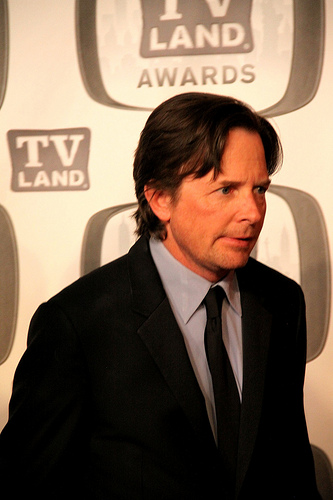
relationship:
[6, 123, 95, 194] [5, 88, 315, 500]
tv land award logo behind man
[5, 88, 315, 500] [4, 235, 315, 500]
man wearing suit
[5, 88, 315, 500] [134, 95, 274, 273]
man has head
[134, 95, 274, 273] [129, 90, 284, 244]
head has hair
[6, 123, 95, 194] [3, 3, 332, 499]
tv land award logo printed on wall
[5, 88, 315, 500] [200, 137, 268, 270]
man has face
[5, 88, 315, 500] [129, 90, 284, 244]
man has hair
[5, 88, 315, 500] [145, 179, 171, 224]
man has ear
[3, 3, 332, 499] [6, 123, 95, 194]
wall has tv land award logo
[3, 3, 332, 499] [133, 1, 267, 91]
wall has logo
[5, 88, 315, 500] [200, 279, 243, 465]
man wearing tie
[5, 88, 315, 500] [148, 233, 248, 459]
man wearing shirt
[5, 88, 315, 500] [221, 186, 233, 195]
man has eye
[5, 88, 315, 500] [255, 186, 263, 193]
man has eye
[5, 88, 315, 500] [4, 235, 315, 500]
man has suit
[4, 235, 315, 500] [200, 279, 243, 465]
suit has tie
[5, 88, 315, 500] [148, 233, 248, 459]
man wears shirt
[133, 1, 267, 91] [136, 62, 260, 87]
logo says awards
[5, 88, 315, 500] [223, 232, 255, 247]
man has mouth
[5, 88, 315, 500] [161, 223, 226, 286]
man has neck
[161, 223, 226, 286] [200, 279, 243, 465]
neck has tie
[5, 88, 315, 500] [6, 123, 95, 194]
man walking past tv land award logo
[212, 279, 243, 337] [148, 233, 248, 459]
shadow on front of shirt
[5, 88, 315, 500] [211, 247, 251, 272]
man has chin stubble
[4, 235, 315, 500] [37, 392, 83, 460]
suit has crease mark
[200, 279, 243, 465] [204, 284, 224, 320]
tie has knot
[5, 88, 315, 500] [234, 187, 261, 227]
man has nose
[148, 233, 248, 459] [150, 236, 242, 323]
shirt has collar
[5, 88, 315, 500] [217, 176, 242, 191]
man has eyebrow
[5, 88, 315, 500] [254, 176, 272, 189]
man has eyebrow